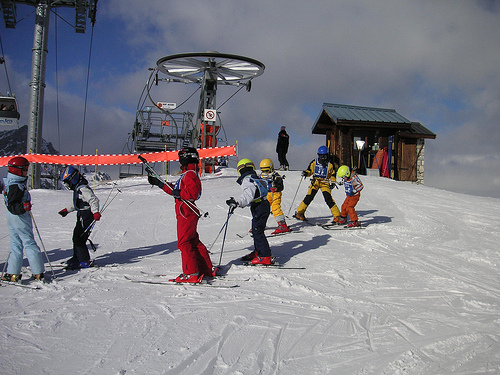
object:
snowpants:
[263, 190, 284, 220]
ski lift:
[116, 48, 271, 178]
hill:
[0, 166, 499, 374]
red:
[187, 211, 191, 228]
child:
[0, 147, 58, 285]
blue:
[20, 220, 36, 244]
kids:
[226, 155, 273, 271]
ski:
[226, 262, 311, 274]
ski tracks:
[310, 298, 403, 373]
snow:
[0, 167, 499, 374]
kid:
[49, 157, 107, 272]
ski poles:
[73, 178, 121, 252]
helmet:
[59, 160, 82, 183]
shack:
[304, 100, 430, 186]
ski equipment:
[350, 131, 397, 180]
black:
[278, 133, 287, 149]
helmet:
[279, 121, 290, 132]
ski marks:
[241, 290, 362, 374]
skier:
[135, 141, 227, 289]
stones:
[414, 155, 423, 164]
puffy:
[410, 117, 500, 198]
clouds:
[103, 0, 499, 198]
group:
[0, 167, 499, 374]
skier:
[253, 153, 293, 234]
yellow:
[270, 196, 281, 210]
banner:
[0, 141, 243, 169]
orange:
[111, 154, 129, 160]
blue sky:
[1, 0, 498, 204]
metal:
[34, 20, 41, 40]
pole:
[19, 0, 52, 190]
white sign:
[199, 108, 219, 122]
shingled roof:
[320, 101, 414, 128]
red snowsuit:
[160, 167, 215, 286]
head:
[53, 160, 86, 191]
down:
[59, 180, 73, 195]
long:
[216, 207, 229, 271]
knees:
[302, 193, 316, 203]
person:
[268, 123, 294, 173]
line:
[341, 225, 498, 304]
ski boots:
[246, 252, 277, 269]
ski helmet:
[174, 145, 198, 167]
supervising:
[278, 131, 287, 139]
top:
[286, 163, 304, 176]